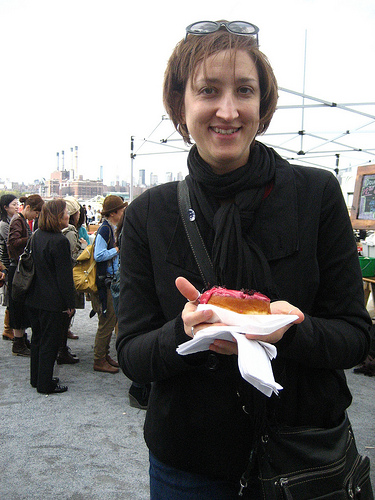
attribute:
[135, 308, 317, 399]
napkin — white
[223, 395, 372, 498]
bag — black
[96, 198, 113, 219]
hat — brown, beige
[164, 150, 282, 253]
scarf — black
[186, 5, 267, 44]
glass — black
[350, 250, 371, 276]
bucket — green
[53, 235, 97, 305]
backpack — yellow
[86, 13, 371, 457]
woman — holding, carrying, wearing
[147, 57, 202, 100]
hair — brown, cropped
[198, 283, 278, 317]
dessert — red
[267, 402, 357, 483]
purse — black, pocket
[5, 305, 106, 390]
pant — black, brown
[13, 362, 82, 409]
shoe — black, brown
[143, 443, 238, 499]
jean — blue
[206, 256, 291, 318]
cake — food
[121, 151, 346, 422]
suit — black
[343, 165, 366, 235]
chalkboard — sign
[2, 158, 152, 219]
building — city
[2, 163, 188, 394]
people — waiting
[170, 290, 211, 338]
ring — wedding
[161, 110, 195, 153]
earring — silver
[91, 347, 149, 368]
boot — brown